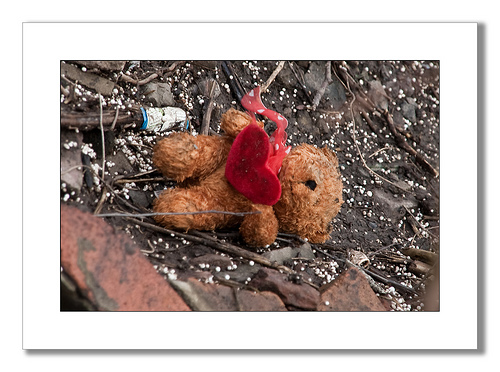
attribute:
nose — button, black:
[307, 176, 318, 188]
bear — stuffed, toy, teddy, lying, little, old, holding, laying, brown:
[153, 106, 344, 247]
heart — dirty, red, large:
[222, 125, 280, 205]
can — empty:
[139, 105, 189, 132]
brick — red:
[61, 201, 193, 312]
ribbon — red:
[241, 85, 287, 149]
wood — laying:
[62, 62, 114, 95]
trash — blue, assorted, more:
[347, 243, 369, 270]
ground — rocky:
[61, 60, 441, 311]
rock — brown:
[374, 185, 416, 214]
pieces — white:
[347, 122, 352, 128]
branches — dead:
[260, 62, 285, 94]